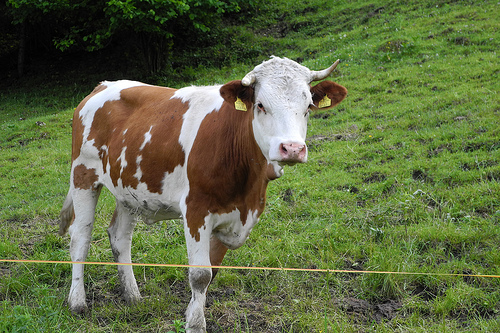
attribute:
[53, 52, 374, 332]
cow — brown, white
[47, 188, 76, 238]
tail — hanging down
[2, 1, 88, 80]
tree — green, in background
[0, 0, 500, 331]
hill — green, grassy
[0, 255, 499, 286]
string — yellow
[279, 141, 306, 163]
nose — pink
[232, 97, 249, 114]
tag — yellow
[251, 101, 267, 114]
eyes — brown